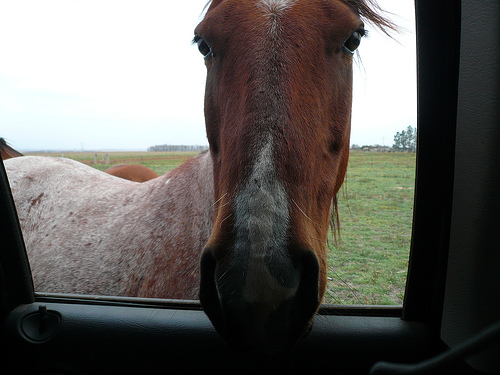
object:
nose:
[193, 244, 327, 333]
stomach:
[42, 223, 184, 292]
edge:
[41, 69, 314, 306]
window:
[0, 0, 421, 311]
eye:
[192, 35, 219, 61]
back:
[19, 151, 164, 218]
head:
[165, 0, 384, 350]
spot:
[225, 128, 298, 264]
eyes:
[339, 24, 367, 54]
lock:
[14, 297, 73, 349]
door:
[14, 280, 320, 349]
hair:
[209, 132, 335, 238]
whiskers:
[257, 201, 338, 260]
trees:
[391, 123, 416, 155]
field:
[349, 152, 402, 301]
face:
[203, 52, 352, 263]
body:
[30, 156, 198, 293]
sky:
[34, 23, 155, 111]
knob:
[376, 339, 443, 372]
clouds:
[14, 31, 187, 146]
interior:
[23, 218, 489, 366]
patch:
[139, 161, 282, 275]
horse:
[0, 0, 371, 335]